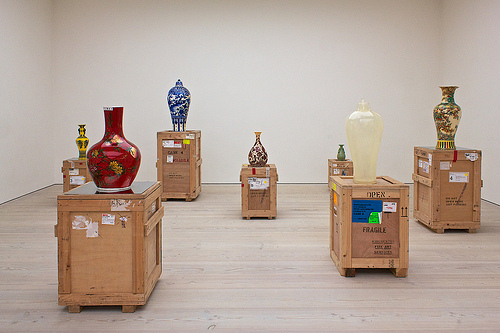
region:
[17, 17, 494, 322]
A large room filled with art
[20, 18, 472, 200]
The rooms walls are white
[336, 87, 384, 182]
The clear vase is white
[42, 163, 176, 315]
The vase is on top of a crate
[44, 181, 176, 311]
The crate is wood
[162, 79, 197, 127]
White and blue vase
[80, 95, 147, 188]
Red vase with flowers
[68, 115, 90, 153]
A small yellow vase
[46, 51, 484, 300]
Vases on top of wooden crates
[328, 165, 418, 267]
The crate has different colored labels on its side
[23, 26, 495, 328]
Seven wooden crates.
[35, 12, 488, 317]
Seven different vases on top crates.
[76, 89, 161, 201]
A red vase with yellow flowers.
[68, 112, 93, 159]
A yellow vase.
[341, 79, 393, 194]
A tall solide color vase.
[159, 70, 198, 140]
A blue and white vase.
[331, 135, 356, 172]
A small green vase.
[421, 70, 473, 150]
A green and white vase.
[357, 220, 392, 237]
The word fragile in black letters.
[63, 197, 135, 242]
White labels on box on left.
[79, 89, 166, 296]
red decorative vase on crate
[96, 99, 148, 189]
red vase with orange flowers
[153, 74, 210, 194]
blue and white vase on crate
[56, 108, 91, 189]
yellow and black vase on crate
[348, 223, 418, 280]
black writing on crate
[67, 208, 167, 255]
labels stuck on crate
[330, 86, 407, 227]
yellow glass vase on crate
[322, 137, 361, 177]
green glass on crate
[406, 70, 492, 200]
beige, green, and yellow vase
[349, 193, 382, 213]
blue and black label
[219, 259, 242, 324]
The floor is wooden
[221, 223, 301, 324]
The floor is wooden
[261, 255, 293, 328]
The floor is wooden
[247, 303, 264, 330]
The floor is wooden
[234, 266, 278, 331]
The floor is wooden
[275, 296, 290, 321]
The floor is wooden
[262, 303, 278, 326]
The floor is wooden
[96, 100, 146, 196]
ceramic vase is red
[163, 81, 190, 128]
ceramic vase is blue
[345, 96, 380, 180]
glass vase is opaque white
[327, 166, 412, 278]
white vase on wooden crate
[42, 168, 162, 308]
red vase on wooden crate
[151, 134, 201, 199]
blue vase on wooden crate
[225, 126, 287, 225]
vase on crate in center of room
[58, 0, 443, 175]
wall is stark white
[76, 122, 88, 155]
small yellow vase behind red vase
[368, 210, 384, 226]
green label below white vase